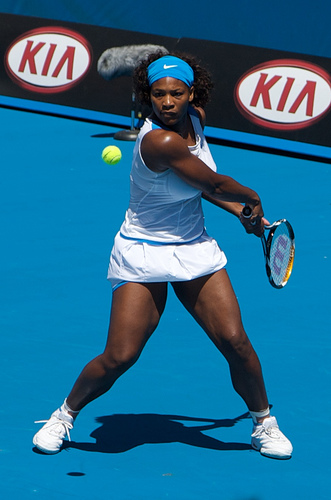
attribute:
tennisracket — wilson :
[240, 203, 297, 294]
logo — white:
[155, 61, 177, 73]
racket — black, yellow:
[256, 209, 301, 282]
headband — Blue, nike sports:
[147, 53, 192, 89]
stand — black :
[88, 49, 176, 144]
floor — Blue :
[4, 107, 324, 493]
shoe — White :
[30, 413, 73, 454]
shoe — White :
[250, 417, 293, 459]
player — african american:
[110, 38, 274, 421]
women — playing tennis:
[41, 41, 299, 450]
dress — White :
[106, 105, 228, 290]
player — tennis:
[31, 53, 293, 458]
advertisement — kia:
[208, 47, 330, 149]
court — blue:
[0, 103, 329, 497]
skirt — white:
[104, 231, 237, 293]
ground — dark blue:
[1, 87, 328, 498]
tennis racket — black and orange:
[238, 202, 299, 292]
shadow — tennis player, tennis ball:
[89, 407, 245, 461]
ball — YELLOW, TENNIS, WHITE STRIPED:
[100, 142, 120, 163]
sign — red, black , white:
[3, 12, 327, 159]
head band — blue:
[137, 54, 194, 88]